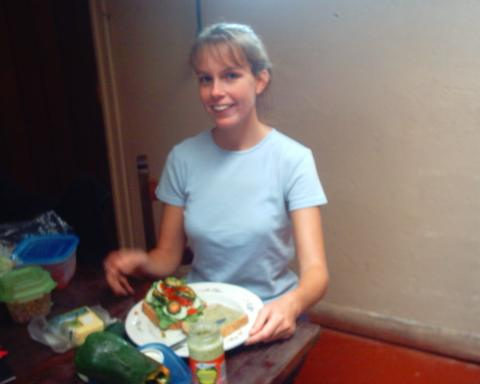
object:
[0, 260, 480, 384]
table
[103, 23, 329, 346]
lady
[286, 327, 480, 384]
floor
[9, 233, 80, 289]
container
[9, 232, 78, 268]
lid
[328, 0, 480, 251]
wall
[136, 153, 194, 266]
chair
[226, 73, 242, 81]
eye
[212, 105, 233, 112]
mouth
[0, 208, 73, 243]
wrapper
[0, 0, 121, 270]
panel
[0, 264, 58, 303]
lid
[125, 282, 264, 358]
plate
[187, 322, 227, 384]
jar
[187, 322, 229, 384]
substance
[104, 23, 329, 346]
bear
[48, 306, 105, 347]
cheese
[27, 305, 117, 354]
bag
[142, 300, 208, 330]
bread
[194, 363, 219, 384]
lable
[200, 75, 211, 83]
eye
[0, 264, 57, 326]
container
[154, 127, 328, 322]
shirt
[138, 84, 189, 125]
wall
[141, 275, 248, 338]
food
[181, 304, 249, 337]
bread